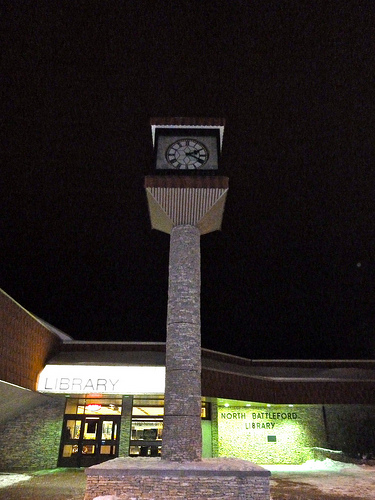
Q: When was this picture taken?
A: At night time.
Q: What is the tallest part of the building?
A: Clock tower.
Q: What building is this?
A: Library.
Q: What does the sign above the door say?
A: Library.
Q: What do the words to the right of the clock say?
A: North Battleford Library.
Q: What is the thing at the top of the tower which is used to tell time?
A: A clock.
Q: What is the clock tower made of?
A: Stone.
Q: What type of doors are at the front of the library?
A: Sliding doors.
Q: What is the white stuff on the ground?
A: Snow.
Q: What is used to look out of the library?
A: Windows.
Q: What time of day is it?
A: Night.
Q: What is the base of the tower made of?
A: Brick.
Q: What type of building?
A: Library.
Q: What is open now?
A: Library.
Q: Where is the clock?
A: On the tower.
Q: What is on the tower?
A: Clock.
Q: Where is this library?
A: North battleford.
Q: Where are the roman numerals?
A: On the clock.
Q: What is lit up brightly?
A: The library.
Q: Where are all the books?
A: Inside the library.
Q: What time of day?
A: It is night time.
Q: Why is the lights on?
A: Because it is dark.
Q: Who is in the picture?
A: No one.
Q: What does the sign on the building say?
A: North Battleford Library.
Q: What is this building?
A: Library.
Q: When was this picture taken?
A: Night time.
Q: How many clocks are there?
A: One.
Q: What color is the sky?
A: Black.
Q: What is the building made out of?
A: Brick.